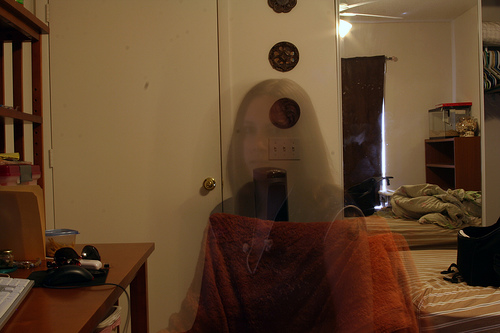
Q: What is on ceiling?
A: Ceiling fan/light.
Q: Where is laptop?
A: Desk.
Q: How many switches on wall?
A: Three.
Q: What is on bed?
A: Purse.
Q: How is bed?
A: Unmade.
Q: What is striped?
A: The sheet.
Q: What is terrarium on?
A: Bookcase.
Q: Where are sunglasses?
A: On desk.